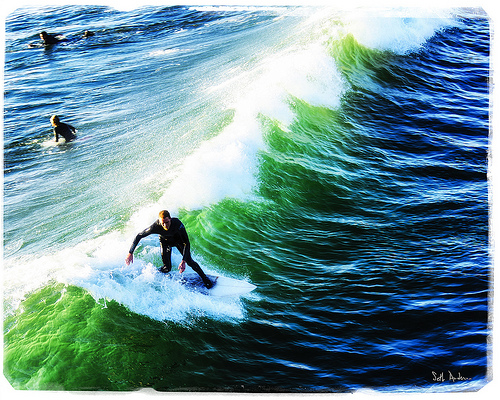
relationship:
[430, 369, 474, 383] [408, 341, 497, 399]
signature in corner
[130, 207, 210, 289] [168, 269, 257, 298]
man standing on a surfboard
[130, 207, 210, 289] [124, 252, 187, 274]
man standing on h hands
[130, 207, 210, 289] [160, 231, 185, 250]
man wearing a black suit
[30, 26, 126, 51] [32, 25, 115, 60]
swimmers are in a group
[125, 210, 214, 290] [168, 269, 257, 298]
man on a surfboard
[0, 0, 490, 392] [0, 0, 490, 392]
lake filtering in lake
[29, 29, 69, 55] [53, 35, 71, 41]
surfer laying on surfboard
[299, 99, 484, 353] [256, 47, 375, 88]
wave have a crest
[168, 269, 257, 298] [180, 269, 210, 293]
surfboard has blue material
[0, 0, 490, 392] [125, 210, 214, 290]
lake has man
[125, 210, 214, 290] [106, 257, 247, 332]
man riding on a wave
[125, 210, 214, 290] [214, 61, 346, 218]
man are waiting for a wave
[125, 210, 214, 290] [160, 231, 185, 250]
man has on a wetsuit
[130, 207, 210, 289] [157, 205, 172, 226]
person has a head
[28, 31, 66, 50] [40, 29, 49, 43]
man has a head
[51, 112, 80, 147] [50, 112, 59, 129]
person has a head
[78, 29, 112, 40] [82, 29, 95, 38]
person has a head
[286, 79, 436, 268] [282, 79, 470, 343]
there is a lake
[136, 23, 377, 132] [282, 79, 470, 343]
here is a lake